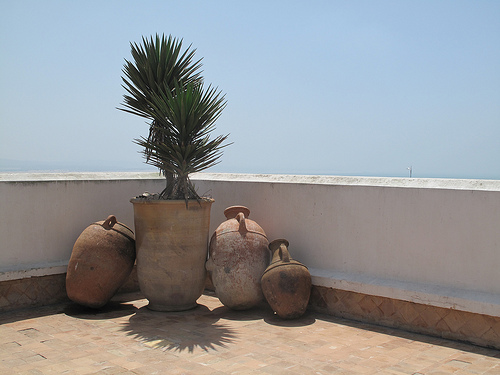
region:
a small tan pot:
[262, 232, 318, 321]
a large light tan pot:
[205, 197, 275, 317]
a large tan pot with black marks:
[64, 210, 140, 304]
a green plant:
[131, 78, 230, 184]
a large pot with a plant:
[127, 185, 216, 312]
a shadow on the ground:
[141, 329, 281, 372]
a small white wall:
[345, 188, 482, 258]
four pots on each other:
[65, 185, 329, 330]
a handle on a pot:
[98, 207, 120, 228]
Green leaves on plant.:
[126, 57, 259, 254]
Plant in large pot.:
[119, 150, 209, 337]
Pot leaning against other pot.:
[50, 194, 217, 320]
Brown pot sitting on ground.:
[263, 232, 330, 342]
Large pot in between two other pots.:
[213, 195, 269, 351]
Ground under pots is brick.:
[101, 287, 316, 373]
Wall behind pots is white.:
[302, 154, 429, 319]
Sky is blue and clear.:
[283, 103, 448, 176]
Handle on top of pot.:
[98, 211, 135, 270]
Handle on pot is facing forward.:
[228, 207, 255, 277]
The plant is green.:
[98, 32, 226, 190]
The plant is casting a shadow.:
[122, 301, 249, 354]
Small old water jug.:
[256, 223, 330, 325]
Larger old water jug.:
[205, 187, 278, 319]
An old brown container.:
[43, 191, 143, 318]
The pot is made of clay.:
[123, 187, 230, 325]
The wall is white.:
[342, 185, 499, 293]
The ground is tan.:
[43, 324, 405, 374]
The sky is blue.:
[283, 27, 436, 121]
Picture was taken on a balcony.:
[3, 12, 495, 374]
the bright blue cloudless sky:
[1, 0, 498, 190]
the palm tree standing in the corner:
[113, 38, 230, 194]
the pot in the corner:
[131, 192, 212, 311]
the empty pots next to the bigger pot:
[212, 199, 314, 321]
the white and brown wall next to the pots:
[1, 167, 498, 354]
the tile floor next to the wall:
[4, 290, 497, 372]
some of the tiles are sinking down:
[13, 314, 61, 371]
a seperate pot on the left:
[62, 209, 130, 311]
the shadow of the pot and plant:
[130, 307, 231, 358]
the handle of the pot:
[230, 211, 250, 234]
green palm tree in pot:
[106, 31, 226, 318]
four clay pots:
[45, 41, 327, 343]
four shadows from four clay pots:
[72, 291, 325, 361]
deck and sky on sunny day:
[10, 31, 365, 362]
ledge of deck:
[191, 161, 477, 311]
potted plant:
[129, 62, 229, 318]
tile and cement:
[8, 167, 360, 374]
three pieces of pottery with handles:
[55, 206, 335, 336]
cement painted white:
[296, 170, 472, 277]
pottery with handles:
[210, 196, 336, 330]